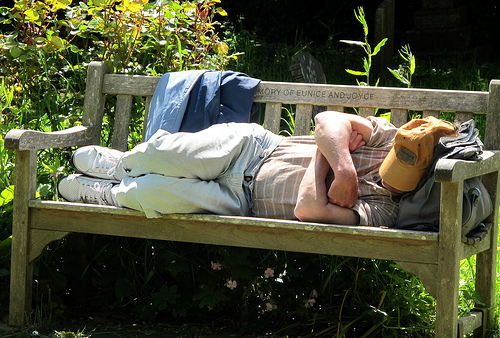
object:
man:
[56, 110, 461, 228]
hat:
[378, 115, 456, 196]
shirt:
[252, 116, 404, 228]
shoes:
[56, 172, 128, 208]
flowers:
[209, 261, 227, 273]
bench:
[1, 59, 499, 337]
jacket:
[144, 70, 261, 143]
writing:
[256, 86, 374, 100]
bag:
[397, 117, 493, 235]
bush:
[0, 0, 247, 221]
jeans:
[113, 120, 287, 219]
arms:
[313, 110, 373, 170]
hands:
[326, 179, 359, 208]